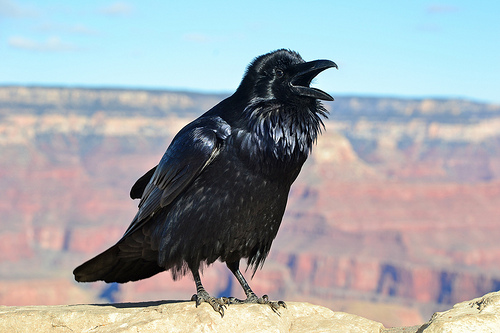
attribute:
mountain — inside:
[3, 85, 498, 332]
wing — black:
[119, 114, 224, 242]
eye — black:
[273, 67, 287, 78]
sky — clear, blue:
[2, 3, 500, 101]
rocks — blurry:
[1, 84, 499, 302]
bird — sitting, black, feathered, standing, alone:
[71, 44, 344, 315]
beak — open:
[287, 57, 345, 105]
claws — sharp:
[198, 290, 291, 320]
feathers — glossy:
[76, 100, 321, 285]